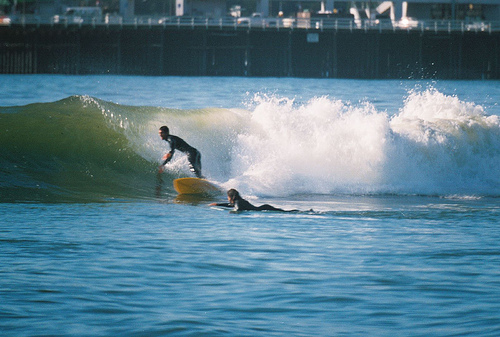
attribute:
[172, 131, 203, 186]
suit — blue, white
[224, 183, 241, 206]
hair — brown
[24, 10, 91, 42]
airplane — blue, white, striped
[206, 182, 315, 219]
surfer — paddling out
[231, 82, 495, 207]
wave — white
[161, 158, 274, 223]
pole — wooden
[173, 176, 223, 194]
surfboard — yellow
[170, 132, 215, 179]
suit — wet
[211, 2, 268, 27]
van — white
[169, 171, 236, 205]
surfboard — long, yellow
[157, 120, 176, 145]
hair — short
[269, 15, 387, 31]
fence — white, long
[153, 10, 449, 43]
bridge — long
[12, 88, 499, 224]
wave — small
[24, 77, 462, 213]
wave — large, crashing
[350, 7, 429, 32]
airplane — blue, white, striped